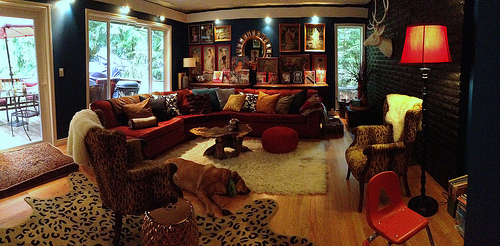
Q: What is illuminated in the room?
A: Lights.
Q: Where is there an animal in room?
A: On floor.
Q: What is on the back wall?
A: Framed pictures.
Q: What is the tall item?
A: The floor lamp.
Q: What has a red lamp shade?
A: The standing pole lamp.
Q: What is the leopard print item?
A: The animal skin rug.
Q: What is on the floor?
A: The furry white rug.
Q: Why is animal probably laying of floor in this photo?
A: Sleeping.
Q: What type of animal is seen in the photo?
A: Dog.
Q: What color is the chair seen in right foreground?
A: Red.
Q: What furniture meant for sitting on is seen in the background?
A: Sofa.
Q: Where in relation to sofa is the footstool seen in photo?
A: In front.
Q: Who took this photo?
A: Photographer.